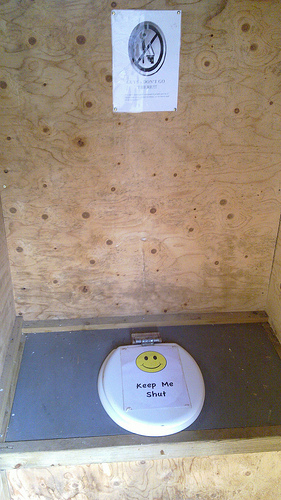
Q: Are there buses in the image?
A: No, there are no buses.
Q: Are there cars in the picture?
A: No, there are no cars.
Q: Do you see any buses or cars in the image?
A: No, there are no cars or buses.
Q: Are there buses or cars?
A: No, there are no cars or buses.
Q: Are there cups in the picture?
A: No, there are no cups.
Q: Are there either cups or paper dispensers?
A: No, there are no cups or paper dispensers.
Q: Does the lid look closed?
A: Yes, the lid is closed.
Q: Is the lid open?
A: No, the lid is closed.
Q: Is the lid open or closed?
A: The lid is closed.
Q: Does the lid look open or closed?
A: The lid is closed.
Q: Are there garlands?
A: No, there are no garlands.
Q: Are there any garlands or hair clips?
A: No, there are no garlands or hair clips.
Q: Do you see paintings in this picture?
A: No, there are no paintings.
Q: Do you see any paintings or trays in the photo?
A: No, there are no paintings or trays.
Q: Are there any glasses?
A: No, there are no glasses.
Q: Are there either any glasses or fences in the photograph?
A: No, there are no glasses or fences.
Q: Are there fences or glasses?
A: No, there are no glasses or fences.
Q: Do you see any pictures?
A: No, there are no pictures.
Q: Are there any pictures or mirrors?
A: No, there are no pictures or mirrors.